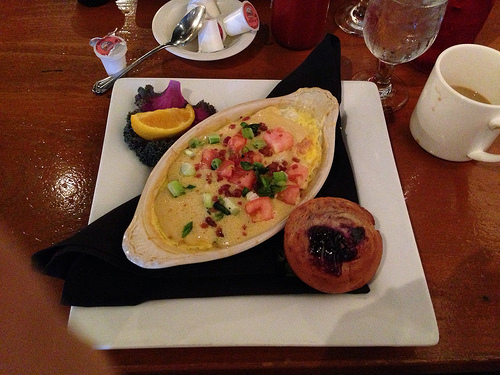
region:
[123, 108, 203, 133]
A slice of an orange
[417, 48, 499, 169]
Coffee cup holding a beverage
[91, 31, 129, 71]
White packet of creamer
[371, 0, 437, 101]
Glass with condensation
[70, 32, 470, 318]
Meal served on white, square plate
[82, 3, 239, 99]
silver spoon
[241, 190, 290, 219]
Slice of tomato topping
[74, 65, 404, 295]
Food placed on top of black cloth napkin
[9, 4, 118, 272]
Wooden table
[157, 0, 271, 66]
Bowl of unopened white creamer packets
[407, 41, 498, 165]
White cup has a drink.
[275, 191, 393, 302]
Pastry with jam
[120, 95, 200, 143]
Slice of orange next to dish.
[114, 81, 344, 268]
Oval dish with creamy food.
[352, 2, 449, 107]
Cup of wine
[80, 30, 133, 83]
Container of concentrated milk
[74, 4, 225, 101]
Spoon on table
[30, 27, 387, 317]
Black napkin under oval dish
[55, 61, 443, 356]
Dish is white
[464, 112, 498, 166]
Handle of cup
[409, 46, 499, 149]
A cup of coffee.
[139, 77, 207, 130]
A lemon and other garnish.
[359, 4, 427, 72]
A cold glass of water.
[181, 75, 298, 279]
Food in a dish.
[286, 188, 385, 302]
Food with a jelly like substance topping.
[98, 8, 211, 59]
A silver spoon to eat with.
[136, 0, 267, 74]
A dish of creamers.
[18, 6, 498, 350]
A large wooden table.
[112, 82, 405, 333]
A black cloth napkin folded into a triangle.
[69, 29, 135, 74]
Empty creamer container.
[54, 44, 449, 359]
square white ceramic dinner plate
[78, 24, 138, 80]
opened creamer pack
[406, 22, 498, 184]
coffee cup with coffee inside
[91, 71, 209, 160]
lemon wedge on green garnish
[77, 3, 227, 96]
stainless steel teaspoon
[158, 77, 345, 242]
diced tomatoes atop an entree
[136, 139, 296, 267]
diced green onions in dish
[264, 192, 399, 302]
blackberry jam on bread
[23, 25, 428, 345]
black cloth napkin on white plate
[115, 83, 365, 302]
cheesy entree in restaurant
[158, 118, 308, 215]
colorful dish containing green onions, tomato, and red topping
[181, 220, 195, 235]
green onion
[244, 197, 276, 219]
chopped piece of tomato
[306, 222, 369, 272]
purple jelly substance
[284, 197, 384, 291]
brown bread filled with purple jelly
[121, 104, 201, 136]
slice of citrus fruit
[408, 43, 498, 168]
white mug containing coffee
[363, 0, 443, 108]
cold glass of water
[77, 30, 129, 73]
container of cream on brown table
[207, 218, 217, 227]
red topping